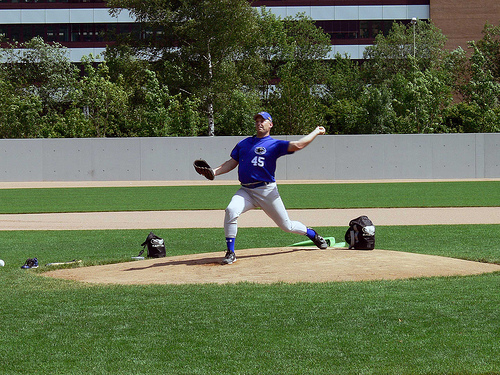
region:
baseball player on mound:
[176, 90, 376, 271]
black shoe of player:
[301, 225, 328, 256]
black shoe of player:
[213, 241, 243, 268]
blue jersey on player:
[223, 132, 310, 187]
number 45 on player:
[247, 152, 269, 172]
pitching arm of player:
[285, 122, 333, 164]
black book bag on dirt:
[338, 214, 385, 257]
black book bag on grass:
[138, 230, 170, 260]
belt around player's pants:
[238, 179, 275, 189]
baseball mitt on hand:
[178, 154, 213, 184]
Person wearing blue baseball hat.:
[241, 101, 297, 159]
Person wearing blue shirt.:
[233, 155, 302, 193]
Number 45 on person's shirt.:
[244, 150, 314, 202]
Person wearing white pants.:
[224, 191, 273, 226]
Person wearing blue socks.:
[298, 221, 323, 248]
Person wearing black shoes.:
[213, 251, 253, 273]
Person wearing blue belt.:
[243, 177, 280, 202]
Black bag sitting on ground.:
[333, 205, 393, 265]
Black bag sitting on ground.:
[133, 225, 194, 290]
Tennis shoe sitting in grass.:
[14, 249, 49, 271]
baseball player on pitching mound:
[186, 90, 351, 270]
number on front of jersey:
[248, 154, 271, 170]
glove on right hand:
[184, 150, 217, 185]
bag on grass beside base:
[134, 219, 181, 261]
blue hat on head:
[245, 100, 283, 135]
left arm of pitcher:
[285, 119, 330, 168]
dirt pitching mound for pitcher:
[116, 244, 436, 284]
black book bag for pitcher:
[341, 211, 378, 255]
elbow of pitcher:
[288, 135, 305, 159]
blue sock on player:
[225, 234, 243, 261]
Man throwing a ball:
[286, 110, 367, 194]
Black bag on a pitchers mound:
[333, 207, 394, 266]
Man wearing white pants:
[229, 182, 327, 235]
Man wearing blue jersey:
[218, 121, 290, 178]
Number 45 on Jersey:
[248, 156, 266, 170]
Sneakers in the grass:
[22, 243, 41, 280]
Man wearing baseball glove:
[167, 130, 219, 184]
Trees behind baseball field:
[51, 30, 243, 115]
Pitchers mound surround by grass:
[204, 220, 314, 272]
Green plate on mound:
[298, 215, 341, 254]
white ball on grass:
[0, 253, 11, 272]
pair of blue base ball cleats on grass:
[20, 256, 40, 276]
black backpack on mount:
[345, 207, 385, 269]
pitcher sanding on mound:
[192, 99, 338, 280]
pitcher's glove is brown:
[189, 152, 216, 188]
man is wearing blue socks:
[224, 229, 316, 251]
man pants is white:
[219, 182, 308, 236]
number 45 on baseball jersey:
[244, 154, 276, 176]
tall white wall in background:
[2, 137, 497, 176]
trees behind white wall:
[6, 4, 493, 141]